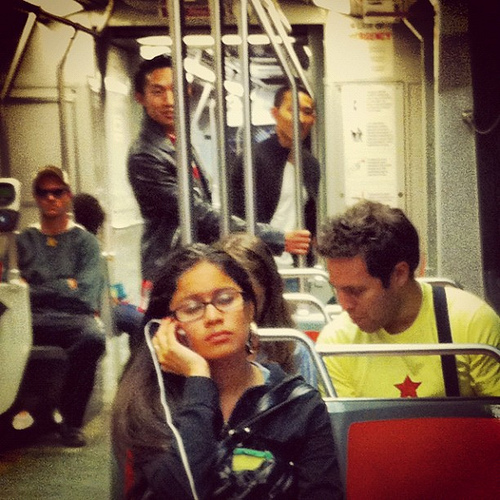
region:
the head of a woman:
[154, 240, 259, 362]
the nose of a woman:
[200, 299, 229, 329]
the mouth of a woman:
[200, 324, 239, 346]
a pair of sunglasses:
[163, 285, 255, 325]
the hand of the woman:
[143, 317, 208, 379]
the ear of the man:
[391, 257, 416, 291]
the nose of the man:
[333, 286, 359, 314]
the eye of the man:
[346, 280, 370, 299]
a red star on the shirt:
[389, 372, 427, 406]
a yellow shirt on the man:
[313, 278, 498, 406]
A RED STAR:
[387, 372, 427, 404]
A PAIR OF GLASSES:
[154, 285, 256, 325]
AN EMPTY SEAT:
[318, 338, 498, 493]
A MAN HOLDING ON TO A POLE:
[116, 68, 316, 279]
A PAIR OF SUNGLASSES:
[29, 183, 72, 204]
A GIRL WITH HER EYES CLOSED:
[101, 240, 353, 497]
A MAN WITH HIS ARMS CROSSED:
[13, 161, 108, 456]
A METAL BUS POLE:
[199, 3, 236, 240]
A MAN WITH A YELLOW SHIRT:
[310, 194, 497, 401]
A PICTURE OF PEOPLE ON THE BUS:
[8, 1, 495, 493]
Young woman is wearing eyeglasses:
[158, 258, 258, 347]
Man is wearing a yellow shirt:
[297, 191, 499, 404]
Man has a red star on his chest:
[377, 357, 431, 409]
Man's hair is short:
[290, 186, 426, 342]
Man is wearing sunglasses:
[18, 165, 78, 212]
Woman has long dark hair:
[103, 241, 286, 453]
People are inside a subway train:
[4, 24, 494, 491]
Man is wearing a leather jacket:
[121, 54, 290, 291]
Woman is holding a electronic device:
[138, 305, 218, 388]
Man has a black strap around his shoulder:
[426, 267, 478, 400]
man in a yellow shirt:
[317, 181, 496, 438]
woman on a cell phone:
[116, 251, 339, 497]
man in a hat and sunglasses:
[10, 136, 107, 446]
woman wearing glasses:
[129, 246, 342, 498]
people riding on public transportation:
[9, 6, 496, 482]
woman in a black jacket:
[109, 250, 356, 498]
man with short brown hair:
[292, 190, 498, 435]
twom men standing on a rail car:
[117, 46, 312, 243]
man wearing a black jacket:
[99, 35, 256, 242]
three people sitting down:
[120, 228, 488, 488]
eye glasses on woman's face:
[165, 285, 249, 326]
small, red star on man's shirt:
[392, 372, 424, 399]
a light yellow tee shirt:
[311, 280, 498, 397]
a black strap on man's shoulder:
[427, 282, 462, 399]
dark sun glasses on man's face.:
[31, 187, 67, 199]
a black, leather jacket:
[126, 116, 288, 278]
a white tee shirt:
[267, 156, 311, 268]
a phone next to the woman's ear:
[148, 319, 191, 349]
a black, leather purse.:
[209, 382, 323, 499]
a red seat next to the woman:
[344, 395, 498, 498]